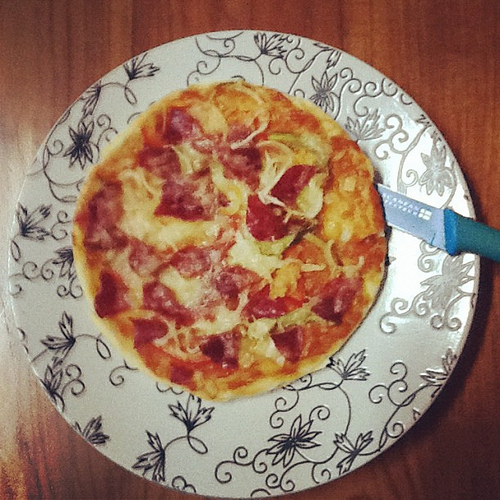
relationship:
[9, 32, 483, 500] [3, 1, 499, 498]
plate on top of table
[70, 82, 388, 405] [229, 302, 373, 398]
pizza has crust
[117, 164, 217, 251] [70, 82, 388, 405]
cheese on pizza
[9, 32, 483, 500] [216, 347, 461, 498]
plate has design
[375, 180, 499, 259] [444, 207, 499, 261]
knife has handle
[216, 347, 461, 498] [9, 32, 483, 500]
design on plate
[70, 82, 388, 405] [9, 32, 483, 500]
pizza on plate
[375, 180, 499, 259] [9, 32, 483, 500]
knife on plate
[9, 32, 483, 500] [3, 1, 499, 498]
plate on table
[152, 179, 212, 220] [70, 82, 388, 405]
pepperoni on pizza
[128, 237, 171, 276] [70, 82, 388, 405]
pepperoni on pizza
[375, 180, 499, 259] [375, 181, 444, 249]
knife has blade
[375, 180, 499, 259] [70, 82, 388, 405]
knife under pizza